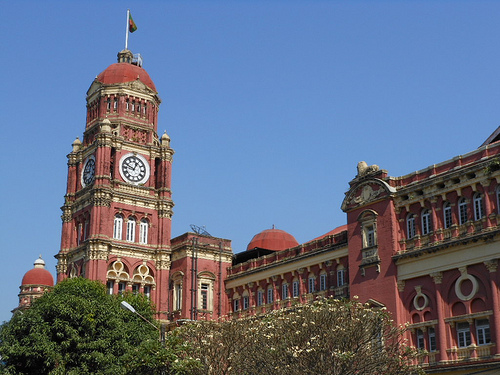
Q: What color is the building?
A: The building is red.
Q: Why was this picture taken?
A: To show how the building looks.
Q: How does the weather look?
A: The weather looks nice and sunny.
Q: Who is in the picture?
A: Nobody is in the picture.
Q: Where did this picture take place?
A: This picture took place outside a big building.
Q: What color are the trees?
A: The trees are green.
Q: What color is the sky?
A: The sky is blue.